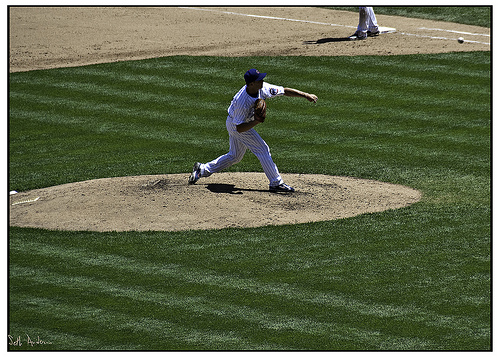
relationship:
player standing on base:
[338, 13, 405, 50] [373, 24, 396, 34]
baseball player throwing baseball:
[188, 67, 318, 195] [456, 35, 465, 45]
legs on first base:
[343, 9, 378, 41] [372, 22, 396, 34]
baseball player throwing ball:
[188, 67, 318, 195] [450, 33, 465, 48]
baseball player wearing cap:
[188, 67, 318, 195] [243, 67, 267, 83]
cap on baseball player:
[243, 67, 267, 83] [188, 67, 318, 195]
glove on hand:
[252, 93, 272, 128] [307, 88, 321, 101]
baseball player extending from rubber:
[188, 67, 318, 195] [140, 175, 163, 189]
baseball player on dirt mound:
[188, 67, 318, 195] [11, 167, 420, 232]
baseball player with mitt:
[188, 67, 318, 195] [247, 96, 274, 129]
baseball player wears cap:
[188, 67, 318, 195] [242, 69, 269, 83]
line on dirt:
[184, 0, 447, 40] [5, 0, 491, 75]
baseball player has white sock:
[188, 67, 318, 195] [210, 124, 282, 184]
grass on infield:
[8, 57, 488, 344] [13, 6, 486, 347]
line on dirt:
[184, 0, 440, 53] [68, 10, 171, 66]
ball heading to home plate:
[455, 35, 464, 44] [356, 15, 405, 38]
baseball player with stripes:
[188, 67, 318, 195] [232, 120, 282, 185]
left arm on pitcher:
[268, 83, 325, 115] [177, 42, 344, 221]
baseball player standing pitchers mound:
[188, 67, 318, 195] [13, 168, 424, 233]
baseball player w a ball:
[188, 67, 318, 195] [455, 35, 464, 44]